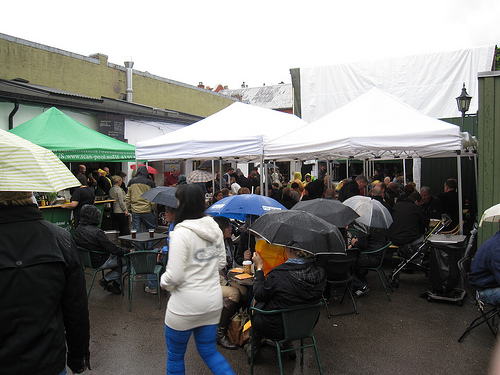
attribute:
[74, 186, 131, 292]
man — sit 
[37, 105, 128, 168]
umbrella — green, open, stripes, red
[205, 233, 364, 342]
person — sitting, holding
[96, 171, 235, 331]
lady — walking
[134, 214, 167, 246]
cup — brown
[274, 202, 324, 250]
umbrella — gray, black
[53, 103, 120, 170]
tent — green, pop up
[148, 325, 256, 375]
pant — blue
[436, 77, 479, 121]
light — black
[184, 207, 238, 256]
shirt — hooded, back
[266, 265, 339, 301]
jacket — black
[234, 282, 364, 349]
chair — outdoor, metal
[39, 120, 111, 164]
canopy — green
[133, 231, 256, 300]
woman — wearing, wear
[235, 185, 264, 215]
umbrella — blue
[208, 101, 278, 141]
umbrella — white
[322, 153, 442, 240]
people — wearing, sit, many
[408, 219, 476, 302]
garbage — can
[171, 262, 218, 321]
jacket — white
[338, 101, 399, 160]
canopy — white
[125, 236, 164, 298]
table — black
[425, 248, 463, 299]
trash — can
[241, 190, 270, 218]
umbrella — blue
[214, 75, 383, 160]
awning — white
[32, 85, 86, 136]
awning — green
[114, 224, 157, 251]
beer — glass